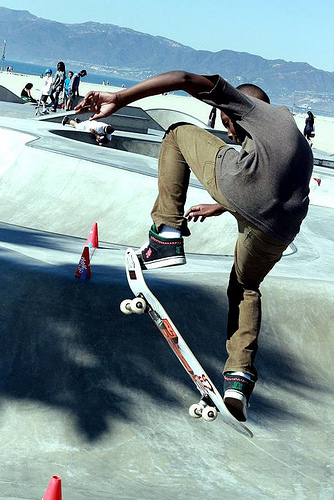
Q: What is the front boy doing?
A: Skateboard trick.